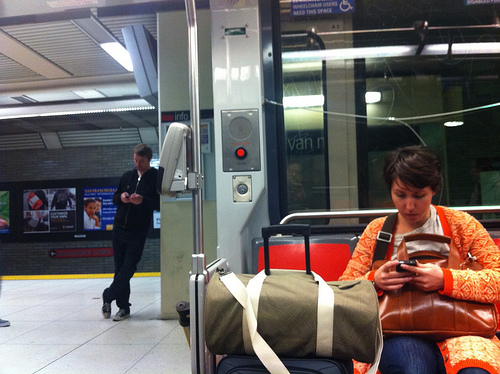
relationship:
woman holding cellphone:
[336, 143, 498, 374] [393, 258, 417, 279]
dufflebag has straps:
[204, 268, 386, 373] [217, 265, 385, 374]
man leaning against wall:
[102, 143, 163, 323] [154, 10, 219, 321]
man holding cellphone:
[102, 143, 163, 323] [124, 191, 132, 200]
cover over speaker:
[220, 106, 261, 174] [229, 115, 253, 139]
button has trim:
[236, 148, 244, 157] [234, 146, 247, 160]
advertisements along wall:
[1, 183, 160, 237] [1, 139, 160, 274]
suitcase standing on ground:
[214, 351, 350, 373] [1, 275, 191, 373]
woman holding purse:
[336, 143, 498, 374] [373, 232, 497, 338]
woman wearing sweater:
[336, 143, 498, 374] [336, 204, 498, 372]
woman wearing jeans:
[336, 143, 498, 374] [377, 335, 489, 373]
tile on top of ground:
[34, 344, 154, 373] [1, 275, 191, 373]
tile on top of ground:
[5, 318, 116, 345] [1, 275, 191, 373]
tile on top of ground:
[87, 317, 178, 344] [1, 275, 191, 373]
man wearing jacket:
[102, 143, 163, 323] [112, 167, 161, 230]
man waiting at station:
[102, 143, 163, 323] [0, 0, 498, 373]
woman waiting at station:
[336, 143, 498, 374] [0, 0, 498, 373]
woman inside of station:
[336, 143, 498, 374] [0, 0, 498, 373]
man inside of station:
[102, 143, 163, 323] [0, 0, 498, 373]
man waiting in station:
[102, 143, 163, 323] [0, 0, 498, 373]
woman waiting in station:
[336, 143, 498, 374] [0, 0, 498, 373]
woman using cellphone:
[336, 143, 498, 374] [393, 258, 417, 279]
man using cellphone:
[102, 143, 163, 323] [124, 191, 132, 200]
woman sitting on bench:
[336, 143, 498, 374] [190, 201, 499, 372]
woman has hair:
[336, 143, 498, 374] [384, 143, 441, 194]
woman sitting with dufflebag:
[336, 143, 498, 374] [204, 268, 387, 373]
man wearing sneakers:
[102, 143, 163, 323] [99, 296, 132, 324]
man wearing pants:
[102, 143, 163, 323] [102, 223, 147, 309]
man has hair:
[102, 143, 163, 323] [134, 142, 153, 164]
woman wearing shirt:
[336, 143, 498, 374] [390, 203, 450, 260]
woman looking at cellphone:
[336, 143, 498, 374] [393, 258, 417, 279]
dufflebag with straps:
[204, 268, 386, 373] [217, 265, 385, 374]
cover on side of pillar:
[220, 106, 261, 174] [206, 1, 269, 278]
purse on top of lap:
[373, 232, 497, 338] [379, 329, 497, 374]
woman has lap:
[336, 143, 498, 374] [379, 329, 497, 374]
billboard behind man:
[81, 186, 123, 231] [102, 143, 163, 323]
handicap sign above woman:
[290, 0, 357, 19] [336, 143, 498, 374]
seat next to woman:
[250, 233, 357, 287] [336, 143, 498, 374]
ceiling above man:
[0, 0, 208, 107] [102, 143, 163, 323]